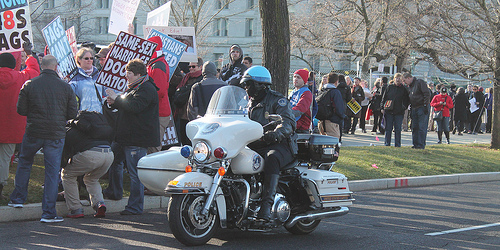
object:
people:
[0, 43, 499, 224]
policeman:
[239, 63, 296, 217]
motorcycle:
[135, 85, 355, 245]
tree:
[260, 0, 290, 97]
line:
[395, 179, 398, 189]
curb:
[346, 170, 499, 194]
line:
[400, 179, 403, 188]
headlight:
[192, 141, 212, 164]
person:
[0, 40, 41, 205]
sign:
[0, 1, 34, 53]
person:
[67, 47, 109, 115]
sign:
[39, 15, 80, 83]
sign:
[95, 31, 157, 92]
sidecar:
[138, 145, 194, 197]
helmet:
[240, 65, 273, 85]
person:
[286, 67, 313, 128]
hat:
[294, 68, 309, 84]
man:
[64, 110, 113, 219]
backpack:
[69, 112, 114, 146]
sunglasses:
[85, 56, 94, 60]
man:
[350, 76, 365, 135]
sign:
[346, 97, 362, 115]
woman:
[430, 87, 454, 141]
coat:
[430, 93, 453, 118]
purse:
[431, 95, 448, 120]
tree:
[288, 1, 499, 147]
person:
[451, 87, 471, 136]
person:
[469, 85, 484, 134]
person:
[370, 77, 383, 133]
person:
[361, 80, 373, 133]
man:
[217, 44, 247, 83]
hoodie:
[219, 44, 248, 85]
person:
[380, 72, 409, 146]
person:
[316, 72, 346, 154]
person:
[402, 72, 430, 151]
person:
[16, 55, 79, 223]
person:
[103, 60, 159, 214]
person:
[187, 59, 229, 119]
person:
[147, 38, 171, 149]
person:
[173, 56, 203, 146]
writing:
[40, 19, 76, 79]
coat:
[15, 70, 77, 137]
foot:
[6, 202, 26, 210]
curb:
[0, 194, 174, 226]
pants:
[62, 147, 113, 212]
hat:
[441, 87, 447, 92]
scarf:
[290, 85, 311, 110]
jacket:
[64, 66, 107, 114]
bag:
[383, 100, 392, 110]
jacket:
[114, 80, 160, 147]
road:
[0, 174, 500, 250]